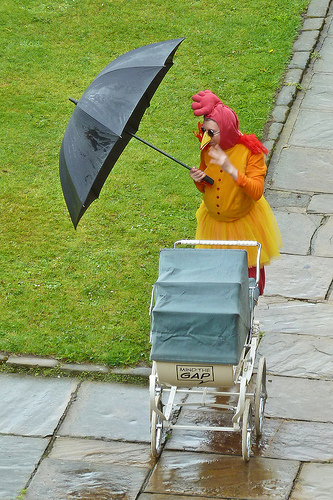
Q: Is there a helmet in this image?
A: No, there are no helmets.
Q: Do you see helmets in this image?
A: No, there are no helmets.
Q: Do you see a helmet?
A: No, there are no helmets.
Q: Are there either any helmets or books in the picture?
A: No, there are no helmets or books.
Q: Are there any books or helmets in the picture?
A: No, there are no helmets or books.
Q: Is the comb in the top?
A: Yes, the comb is in the top of the image.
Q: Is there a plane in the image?
A: No, there are no airplanes.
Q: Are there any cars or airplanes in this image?
A: No, there are no airplanes or cars.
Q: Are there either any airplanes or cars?
A: No, there are no airplanes or cars.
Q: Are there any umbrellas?
A: Yes, there is an umbrella.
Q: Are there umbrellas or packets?
A: Yes, there is an umbrella.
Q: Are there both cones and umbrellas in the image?
A: No, there is an umbrella but no cones.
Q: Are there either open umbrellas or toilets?
A: Yes, there is an open umbrella.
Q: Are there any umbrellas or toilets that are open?
A: Yes, the umbrella is open.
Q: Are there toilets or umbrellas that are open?
A: Yes, the umbrella is open.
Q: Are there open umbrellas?
A: Yes, there is an open umbrella.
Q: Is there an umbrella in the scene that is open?
A: Yes, there is an umbrella that is open.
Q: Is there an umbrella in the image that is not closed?
A: Yes, there is a open umbrella.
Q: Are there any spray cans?
A: No, there are no spray cans.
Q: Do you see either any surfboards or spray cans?
A: No, there are no spray cans or surfboards.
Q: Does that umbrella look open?
A: Yes, the umbrella is open.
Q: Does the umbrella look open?
A: Yes, the umbrella is open.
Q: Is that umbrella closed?
A: No, the umbrella is open.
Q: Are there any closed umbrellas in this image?
A: No, there is an umbrella but it is open.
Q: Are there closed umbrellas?
A: No, there is an umbrella but it is open.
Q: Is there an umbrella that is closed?
A: No, there is an umbrella but it is open.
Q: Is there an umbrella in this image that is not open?
A: No, there is an umbrella but it is open.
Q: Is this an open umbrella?
A: Yes, this is an open umbrella.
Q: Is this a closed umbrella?
A: No, this is an open umbrella.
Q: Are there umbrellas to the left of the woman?
A: Yes, there is an umbrella to the left of the woman.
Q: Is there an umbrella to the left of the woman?
A: Yes, there is an umbrella to the left of the woman.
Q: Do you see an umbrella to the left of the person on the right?
A: Yes, there is an umbrella to the left of the woman.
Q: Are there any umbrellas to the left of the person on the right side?
A: Yes, there is an umbrella to the left of the woman.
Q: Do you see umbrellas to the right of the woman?
A: No, the umbrella is to the left of the woman.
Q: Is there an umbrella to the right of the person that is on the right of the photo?
A: No, the umbrella is to the left of the woman.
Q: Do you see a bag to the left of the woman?
A: No, there is an umbrella to the left of the woman.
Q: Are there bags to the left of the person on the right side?
A: No, there is an umbrella to the left of the woman.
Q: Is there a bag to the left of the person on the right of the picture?
A: No, there is an umbrella to the left of the woman.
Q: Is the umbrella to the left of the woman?
A: Yes, the umbrella is to the left of the woman.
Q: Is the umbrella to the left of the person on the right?
A: Yes, the umbrella is to the left of the woman.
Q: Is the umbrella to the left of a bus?
A: No, the umbrella is to the left of the woman.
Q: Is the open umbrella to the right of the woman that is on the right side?
A: No, the umbrella is to the left of the woman.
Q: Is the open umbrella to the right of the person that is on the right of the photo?
A: No, the umbrella is to the left of the woman.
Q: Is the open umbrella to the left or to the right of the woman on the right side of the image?
A: The umbrella is to the left of the woman.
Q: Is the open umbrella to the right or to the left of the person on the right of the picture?
A: The umbrella is to the left of the woman.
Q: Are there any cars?
A: No, there are no cars.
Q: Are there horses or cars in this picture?
A: No, there are no cars or horses.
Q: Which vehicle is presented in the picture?
A: The vehicle is a carriage.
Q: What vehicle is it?
A: The vehicle is a carriage.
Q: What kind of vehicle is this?
A: This is a carriage.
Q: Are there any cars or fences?
A: No, there are no cars or fences.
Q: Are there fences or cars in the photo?
A: No, there are no cars or fences.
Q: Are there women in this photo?
A: Yes, there is a woman.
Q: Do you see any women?
A: Yes, there is a woman.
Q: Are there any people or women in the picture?
A: Yes, there is a woman.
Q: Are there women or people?
A: Yes, there is a woman.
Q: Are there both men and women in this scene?
A: No, there is a woman but no men.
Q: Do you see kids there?
A: No, there are no kids.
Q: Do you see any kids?
A: No, there are no kids.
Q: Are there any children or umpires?
A: No, there are no children or umpires.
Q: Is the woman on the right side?
A: Yes, the woman is on the right of the image.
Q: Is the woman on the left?
A: No, the woman is on the right of the image.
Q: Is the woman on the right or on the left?
A: The woman is on the right of the image.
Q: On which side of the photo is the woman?
A: The woman is on the right of the image.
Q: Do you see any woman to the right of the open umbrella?
A: Yes, there is a woman to the right of the umbrella.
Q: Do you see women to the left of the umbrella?
A: No, the woman is to the right of the umbrella.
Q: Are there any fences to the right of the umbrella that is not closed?
A: No, there is a woman to the right of the umbrella.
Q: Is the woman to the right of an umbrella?
A: Yes, the woman is to the right of an umbrella.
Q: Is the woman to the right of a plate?
A: No, the woman is to the right of an umbrella.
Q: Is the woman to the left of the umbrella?
A: No, the woman is to the right of the umbrella.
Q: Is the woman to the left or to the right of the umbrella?
A: The woman is to the right of the umbrella.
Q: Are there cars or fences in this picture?
A: No, there are no cars or fences.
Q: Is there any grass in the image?
A: Yes, there is grass.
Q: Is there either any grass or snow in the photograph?
A: Yes, there is grass.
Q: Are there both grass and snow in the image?
A: No, there is grass but no snow.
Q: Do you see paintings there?
A: No, there are no paintings.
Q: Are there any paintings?
A: No, there are no paintings.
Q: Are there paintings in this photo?
A: No, there are no paintings.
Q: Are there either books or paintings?
A: No, there are no paintings or books.